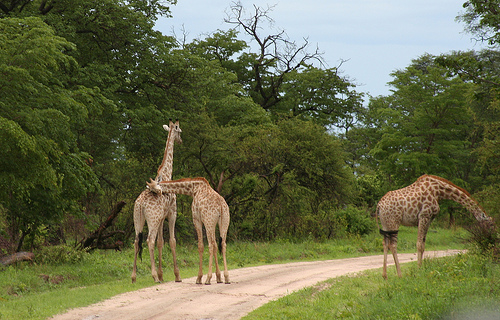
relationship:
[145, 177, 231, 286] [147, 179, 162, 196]
giraffe laying head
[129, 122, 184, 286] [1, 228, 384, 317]
giraffe in grass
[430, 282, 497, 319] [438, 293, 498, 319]
edge of hole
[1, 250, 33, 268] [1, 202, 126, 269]
trunk of tree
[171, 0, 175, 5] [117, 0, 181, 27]
leaf on tree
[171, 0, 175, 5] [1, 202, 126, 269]
leaf on tree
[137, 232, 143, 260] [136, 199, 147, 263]
tip of tail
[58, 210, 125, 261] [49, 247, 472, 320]
brush on side of road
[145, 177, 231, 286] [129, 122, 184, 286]
giraffe nuzzling giraffe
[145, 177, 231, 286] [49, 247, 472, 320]
giraffe in road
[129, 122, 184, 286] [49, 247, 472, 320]
giraffe standing next to road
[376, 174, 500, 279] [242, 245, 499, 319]
giraffe eating grass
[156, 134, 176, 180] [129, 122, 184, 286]
neck of giraffe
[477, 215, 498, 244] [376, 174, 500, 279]
head of giraffe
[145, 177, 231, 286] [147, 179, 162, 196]
giraffe rubbing head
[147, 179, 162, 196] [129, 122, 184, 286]
head on giraffe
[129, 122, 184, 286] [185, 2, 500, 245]
giraffe stand looking forward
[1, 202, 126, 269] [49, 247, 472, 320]
tree on side of road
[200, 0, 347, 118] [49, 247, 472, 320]
tree lines road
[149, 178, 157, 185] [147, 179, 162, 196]
horn on head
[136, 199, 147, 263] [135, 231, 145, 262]
tail has hair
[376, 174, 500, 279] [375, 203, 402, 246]
giraffe using tail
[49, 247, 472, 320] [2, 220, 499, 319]
road on ground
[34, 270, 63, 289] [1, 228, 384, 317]
spot on grass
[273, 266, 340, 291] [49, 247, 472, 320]
line in road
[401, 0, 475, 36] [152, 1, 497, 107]
cloud in sky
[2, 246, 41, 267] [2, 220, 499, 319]
stump on ground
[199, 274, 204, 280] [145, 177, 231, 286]
spot on giraffe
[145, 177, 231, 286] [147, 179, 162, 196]
giraffe resting head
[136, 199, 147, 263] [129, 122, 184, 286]
tail on giraffe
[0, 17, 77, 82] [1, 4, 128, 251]
cluster on trees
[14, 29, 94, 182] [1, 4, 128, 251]
leaves on trees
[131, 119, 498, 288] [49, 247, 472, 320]
cluster on road